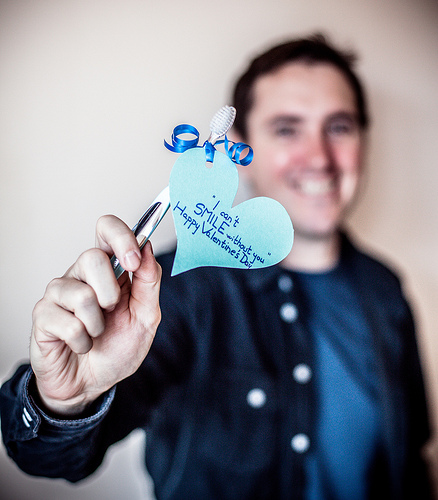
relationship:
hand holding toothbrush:
[24, 207, 167, 420] [26, 82, 261, 420]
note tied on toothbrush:
[167, 143, 293, 272] [106, 125, 310, 301]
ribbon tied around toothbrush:
[163, 123, 253, 166] [91, 99, 263, 296]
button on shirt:
[275, 273, 296, 290] [3, 224, 436, 497]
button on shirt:
[280, 299, 298, 322] [3, 224, 436, 497]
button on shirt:
[292, 361, 312, 383] [3, 224, 436, 497]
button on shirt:
[290, 431, 310, 452] [3, 224, 436, 497]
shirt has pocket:
[3, 224, 436, 497] [202, 373, 285, 474]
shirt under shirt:
[3, 224, 436, 497] [3, 224, 436, 497]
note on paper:
[173, 199, 266, 270] [169, 145, 297, 283]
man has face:
[0, 26, 437, 500] [254, 62, 365, 233]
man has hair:
[0, 26, 437, 500] [227, 34, 369, 138]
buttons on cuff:
[20, 407, 32, 429] [9, 360, 122, 446]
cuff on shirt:
[9, 360, 122, 446] [3, 224, 436, 497]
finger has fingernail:
[95, 217, 139, 269] [121, 248, 142, 271]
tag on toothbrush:
[168, 146, 298, 280] [96, 102, 238, 314]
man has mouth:
[2, 26, 435, 496] [295, 172, 342, 199]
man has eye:
[2, 26, 435, 496] [268, 124, 298, 139]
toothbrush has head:
[112, 105, 239, 279] [206, 104, 244, 138]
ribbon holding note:
[163, 123, 253, 166] [167, 143, 293, 272]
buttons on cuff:
[22, 407, 33, 428] [11, 365, 117, 444]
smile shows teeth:
[290, 171, 341, 203] [296, 176, 336, 192]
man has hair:
[2, 26, 435, 496] [227, 34, 369, 138]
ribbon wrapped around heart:
[162, 123, 251, 166] [170, 146, 293, 277]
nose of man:
[302, 124, 334, 173] [2, 26, 435, 496]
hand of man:
[30, 215, 163, 402] [2, 26, 435, 496]